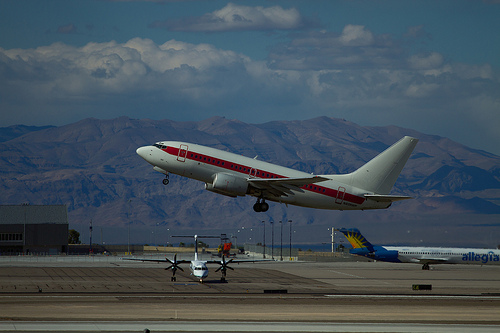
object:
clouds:
[187, 40, 276, 99]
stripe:
[159, 143, 364, 204]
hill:
[0, 107, 500, 237]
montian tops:
[1, 110, 422, 132]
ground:
[441, 185, 451, 205]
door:
[335, 185, 347, 203]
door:
[248, 167, 258, 179]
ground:
[466, 87, 498, 116]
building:
[0, 203, 70, 255]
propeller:
[213, 253, 236, 275]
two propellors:
[162, 247, 236, 277]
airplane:
[123, 234, 238, 284]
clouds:
[337, 5, 400, 50]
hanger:
[3, 200, 68, 257]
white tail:
[331, 135, 418, 192]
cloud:
[164, 0, 307, 34]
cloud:
[1, 36, 87, 72]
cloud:
[338, 64, 394, 94]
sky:
[0, 0, 499, 127]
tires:
[260, 201, 269, 212]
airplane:
[331, 222, 499, 271]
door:
[175, 143, 190, 162]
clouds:
[452, 85, 479, 110]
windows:
[187, 150, 254, 178]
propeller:
[163, 253, 186, 275]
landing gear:
[253, 190, 268, 213]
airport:
[0, 122, 500, 333]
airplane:
[135, 132, 418, 213]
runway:
[0, 295, 500, 330]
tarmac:
[262, 257, 499, 294]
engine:
[221, 260, 229, 270]